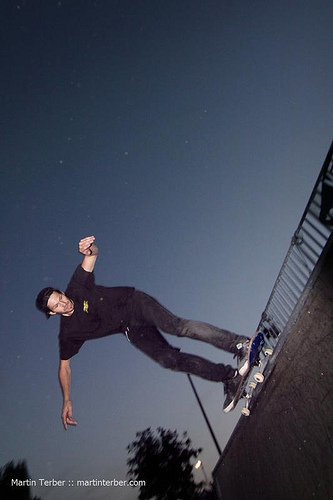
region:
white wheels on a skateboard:
[257, 350, 277, 380]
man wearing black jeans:
[112, 287, 259, 416]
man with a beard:
[54, 302, 76, 313]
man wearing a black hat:
[24, 287, 64, 315]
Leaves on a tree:
[122, 422, 197, 499]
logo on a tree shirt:
[73, 297, 97, 316]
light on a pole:
[190, 459, 204, 470]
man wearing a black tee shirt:
[51, 276, 133, 334]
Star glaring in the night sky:
[41, 145, 181, 211]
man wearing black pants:
[111, 291, 246, 398]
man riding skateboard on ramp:
[36, 235, 271, 430]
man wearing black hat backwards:
[37, 286, 75, 319]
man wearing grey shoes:
[224, 337, 249, 411]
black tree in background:
[129, 427, 212, 499]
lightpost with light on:
[193, 460, 208, 480]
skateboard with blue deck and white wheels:
[233, 334, 273, 414]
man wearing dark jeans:
[129, 289, 249, 382]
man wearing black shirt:
[60, 264, 133, 361]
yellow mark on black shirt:
[83, 300, 88, 314]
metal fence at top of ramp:
[251, 140, 331, 355]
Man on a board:
[224, 325, 275, 421]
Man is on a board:
[218, 328, 273, 417]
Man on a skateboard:
[225, 325, 272, 418]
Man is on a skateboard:
[227, 325, 276, 421]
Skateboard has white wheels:
[237, 348, 275, 418]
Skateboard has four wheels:
[234, 345, 278, 424]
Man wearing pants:
[122, 287, 244, 383]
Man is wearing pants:
[124, 287, 239, 389]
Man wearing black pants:
[123, 287, 240, 379]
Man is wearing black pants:
[122, 288, 241, 385]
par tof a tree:
[164, 447, 177, 465]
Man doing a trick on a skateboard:
[206, 338, 277, 409]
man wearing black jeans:
[115, 293, 229, 390]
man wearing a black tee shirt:
[64, 281, 124, 340]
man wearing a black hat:
[30, 286, 74, 317]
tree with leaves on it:
[125, 424, 213, 498]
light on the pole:
[194, 457, 208, 474]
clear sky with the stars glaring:
[37, 114, 141, 211]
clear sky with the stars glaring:
[180, 101, 260, 186]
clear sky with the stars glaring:
[29, 65, 149, 169]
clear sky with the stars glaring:
[27, 159, 166, 237]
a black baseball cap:
[36, 287, 57, 317]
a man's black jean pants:
[128, 287, 236, 386]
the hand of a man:
[76, 236, 103, 254]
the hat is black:
[37, 286, 55, 318]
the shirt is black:
[57, 264, 135, 360]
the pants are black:
[126, 289, 245, 381]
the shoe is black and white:
[221, 368, 239, 412]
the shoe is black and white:
[232, 334, 249, 373]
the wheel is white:
[252, 372, 263, 382]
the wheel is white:
[263, 349, 272, 355]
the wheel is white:
[240, 405, 250, 415]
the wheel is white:
[248, 381, 256, 388]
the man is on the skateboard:
[35, 235, 271, 431]